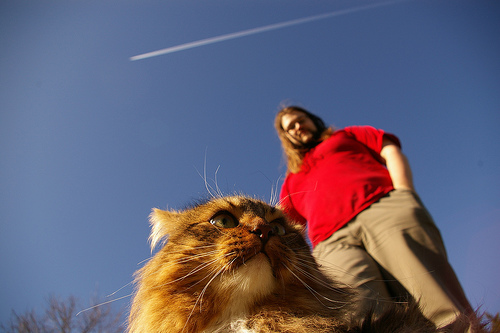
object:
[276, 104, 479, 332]
man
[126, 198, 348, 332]
cat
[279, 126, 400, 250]
shirt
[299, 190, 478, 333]
pants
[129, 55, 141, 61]
plane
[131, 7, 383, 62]
trail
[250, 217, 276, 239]
nose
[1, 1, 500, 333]
sky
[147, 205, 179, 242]
ears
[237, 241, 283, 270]
mouth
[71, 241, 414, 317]
whiskers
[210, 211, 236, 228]
eyes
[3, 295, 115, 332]
tree